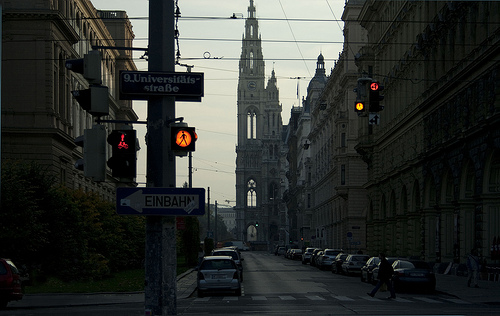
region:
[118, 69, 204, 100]
a street sign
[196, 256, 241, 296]
the back of a silver car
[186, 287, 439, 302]
the white lines of the crosswalk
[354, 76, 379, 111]
a street light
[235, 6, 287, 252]
a tall building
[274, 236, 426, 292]
many cars parked along the street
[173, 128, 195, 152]
a crosswalk light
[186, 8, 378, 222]
wires in the street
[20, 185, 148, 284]
trees and bushes along the street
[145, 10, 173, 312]
a pole holding the signs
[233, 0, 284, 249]
A large intricate building.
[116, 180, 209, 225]
A black and white sign.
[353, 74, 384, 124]
Hanging red street lights.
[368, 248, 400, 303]
A person walking across road.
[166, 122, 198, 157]
A lit up walking light.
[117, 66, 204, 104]
A street name sign.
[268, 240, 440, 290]
Cars parked along the street.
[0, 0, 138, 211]
A large light colored building.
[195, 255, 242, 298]
A light colored car.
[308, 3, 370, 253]
A cream colored building.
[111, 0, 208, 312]
Power cable with signs on it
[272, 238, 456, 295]
Cars parked on the street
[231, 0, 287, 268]
Tall thin tapering building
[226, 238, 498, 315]
Street without moving vehicles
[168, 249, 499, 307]
Pedestrian crossing the street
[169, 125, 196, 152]
Orange sign signaling pedestrian crossing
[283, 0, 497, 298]
Array of buildings on a side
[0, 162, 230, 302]
Long fence vegetation on a street side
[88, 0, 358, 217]
Hazy blue open sky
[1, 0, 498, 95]
Cables running across the street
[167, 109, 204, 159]
orange pedestrian light on poll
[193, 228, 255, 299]
cars parked on street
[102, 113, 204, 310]
traffic signal light on poll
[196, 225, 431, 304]
an empty street with no cars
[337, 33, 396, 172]
a red traffic signal light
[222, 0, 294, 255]
a tall building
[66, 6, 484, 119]
bunch of power lines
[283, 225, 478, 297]
bunch of cars parked on street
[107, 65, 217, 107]
plate with street name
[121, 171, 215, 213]
traffic signs on poll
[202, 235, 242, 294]
cars parked along a street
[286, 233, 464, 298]
cars parked on the side of a street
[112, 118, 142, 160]
a street crossing sign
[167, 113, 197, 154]
a street crossing sign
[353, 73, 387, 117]
a traffic light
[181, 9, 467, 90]
several power lines crossing a street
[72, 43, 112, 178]
a traffic light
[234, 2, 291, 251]
a large building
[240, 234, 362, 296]
a city street